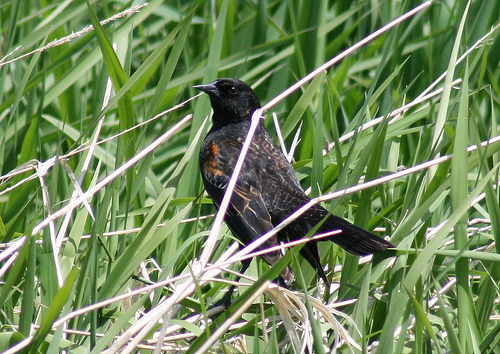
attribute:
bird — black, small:
[191, 78, 396, 314]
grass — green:
[0, 1, 499, 354]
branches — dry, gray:
[120, 1, 496, 317]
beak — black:
[192, 81, 219, 98]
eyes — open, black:
[227, 85, 237, 94]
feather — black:
[299, 243, 331, 289]